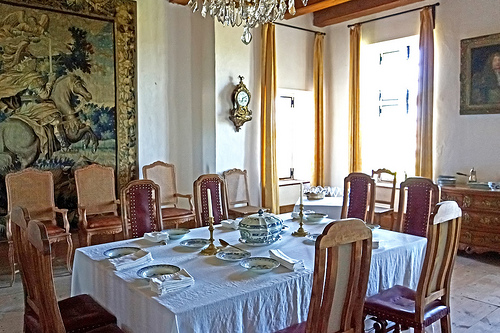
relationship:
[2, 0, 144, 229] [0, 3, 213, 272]
art piece on wall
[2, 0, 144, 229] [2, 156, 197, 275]
art piece behind chairs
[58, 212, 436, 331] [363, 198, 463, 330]
table with chair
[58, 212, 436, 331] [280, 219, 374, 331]
table with chair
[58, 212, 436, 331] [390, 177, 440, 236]
table with chair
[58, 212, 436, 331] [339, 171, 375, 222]
table with chair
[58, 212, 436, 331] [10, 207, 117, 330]
table with chair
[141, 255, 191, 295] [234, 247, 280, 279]
bowl on a bowl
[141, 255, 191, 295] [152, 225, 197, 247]
bowl on a bowl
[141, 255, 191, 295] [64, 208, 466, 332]
bowl on a table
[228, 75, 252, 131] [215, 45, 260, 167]
clock on wall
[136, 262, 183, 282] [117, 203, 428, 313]
bowl sitting on table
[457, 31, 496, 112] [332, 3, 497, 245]
portrait hanging from wall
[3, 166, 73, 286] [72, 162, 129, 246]
chair against chair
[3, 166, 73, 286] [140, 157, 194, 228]
chair against chair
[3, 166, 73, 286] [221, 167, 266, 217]
chair against chair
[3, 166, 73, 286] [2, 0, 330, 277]
chair against wall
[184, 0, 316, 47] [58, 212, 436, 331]
chandelier hanging over table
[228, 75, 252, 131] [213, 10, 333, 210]
clock hanging from wall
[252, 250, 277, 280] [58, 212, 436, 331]
plate sitting on table